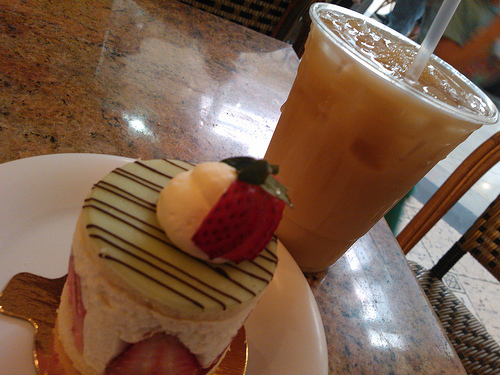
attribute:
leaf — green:
[260, 171, 295, 210]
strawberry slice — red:
[188, 178, 265, 262]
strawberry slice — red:
[220, 193, 276, 264]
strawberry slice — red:
[247, 193, 285, 263]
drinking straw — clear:
[405, 0, 459, 82]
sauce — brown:
[1, 271, 247, 372]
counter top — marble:
[1, 1, 466, 372]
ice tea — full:
[262, 7, 480, 273]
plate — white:
[5, 155, 340, 373]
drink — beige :
[229, 0, 498, 280]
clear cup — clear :
[245, 2, 498, 283]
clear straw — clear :
[395, 2, 463, 78]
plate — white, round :
[0, 129, 347, 373]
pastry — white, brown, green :
[35, 139, 285, 371]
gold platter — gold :
[5, 230, 255, 373]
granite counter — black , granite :
[3, 3, 466, 373]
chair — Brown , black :
[409, 158, 498, 373]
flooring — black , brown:
[357, 90, 497, 370]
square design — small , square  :
[417, 234, 479, 311]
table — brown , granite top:
[4, 0, 452, 367]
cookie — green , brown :
[34, 140, 280, 362]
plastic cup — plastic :
[258, 8, 498, 297]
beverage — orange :
[315, 17, 391, 215]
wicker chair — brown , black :
[435, 194, 497, 318]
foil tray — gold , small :
[17, 264, 70, 338]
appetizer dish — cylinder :
[46, 153, 287, 371]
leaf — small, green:
[221, 155, 280, 188]